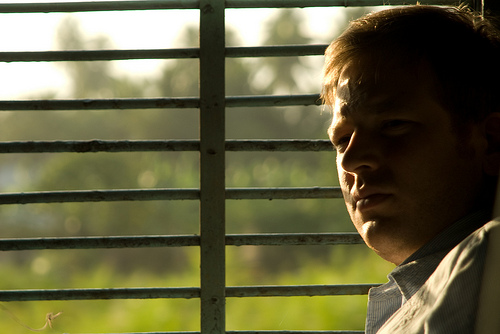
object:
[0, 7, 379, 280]
trees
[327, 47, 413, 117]
forehead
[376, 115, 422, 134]
eye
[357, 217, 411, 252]
chin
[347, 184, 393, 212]
mouth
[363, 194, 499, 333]
collared shirt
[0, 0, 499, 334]
window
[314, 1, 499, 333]
man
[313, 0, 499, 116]
hair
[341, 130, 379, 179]
nose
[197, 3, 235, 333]
pole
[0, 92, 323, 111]
bars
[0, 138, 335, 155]
bars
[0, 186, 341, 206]
bars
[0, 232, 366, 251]
bars